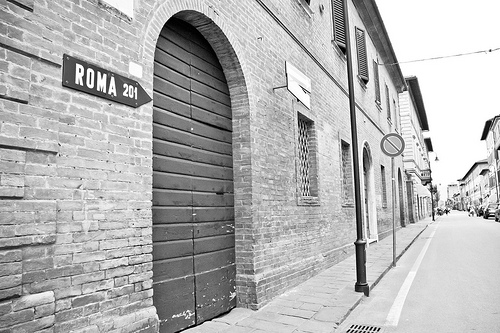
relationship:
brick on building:
[80, 177, 182, 277] [69, 5, 382, 312]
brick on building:
[32, 216, 104, 255] [125, 9, 405, 255]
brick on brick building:
[111, 111, 151, 132] [0, 2, 441, 333]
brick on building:
[18, 102, 60, 126] [78, 15, 396, 238]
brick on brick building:
[20, 136, 77, 166] [32, 14, 455, 320]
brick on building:
[100, 203, 152, 254] [54, 52, 316, 260]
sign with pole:
[376, 134, 410, 159] [383, 158, 401, 269]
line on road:
[395, 260, 415, 315] [350, 208, 495, 330]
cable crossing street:
[380, 50, 484, 64] [434, 220, 488, 322]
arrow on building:
[35, 63, 202, 100] [25, 17, 373, 287]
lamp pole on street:
[340, 3, 376, 294] [440, 231, 477, 329]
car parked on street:
[482, 197, 494, 219] [367, 203, 497, 331]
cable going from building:
[382, 48, 496, 67] [325, 14, 389, 244]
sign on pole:
[380, 133, 406, 157] [379, 132, 404, 262]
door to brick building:
[149, 19, 237, 331] [0, 2, 441, 333]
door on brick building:
[149, 19, 237, 331] [0, 2, 441, 333]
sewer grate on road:
[344, 324, 383, 331] [333, 208, 498, 330]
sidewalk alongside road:
[179, 214, 437, 331] [333, 208, 498, 330]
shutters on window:
[350, 23, 370, 83] [355, 23, 372, 85]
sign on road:
[380, 133, 406, 157] [337, 210, 500, 333]